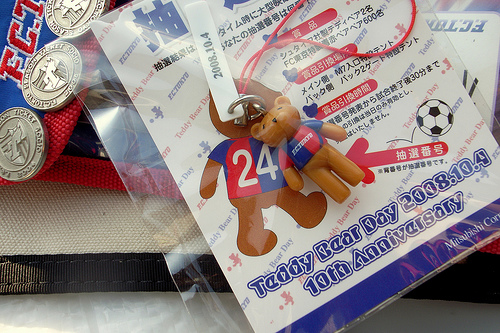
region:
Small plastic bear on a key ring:
[217, 0, 413, 214]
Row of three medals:
[2, 1, 97, 189]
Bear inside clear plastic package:
[54, 3, 489, 325]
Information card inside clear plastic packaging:
[72, 0, 493, 323]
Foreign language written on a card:
[131, 5, 447, 136]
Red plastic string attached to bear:
[222, 0, 419, 202]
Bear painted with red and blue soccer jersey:
[235, 91, 367, 216]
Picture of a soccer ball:
[395, 85, 467, 158]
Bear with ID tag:
[155, 1, 374, 208]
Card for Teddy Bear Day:
[187, 65, 493, 302]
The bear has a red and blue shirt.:
[261, 128, 371, 174]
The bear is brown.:
[227, 72, 371, 224]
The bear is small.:
[246, 98, 381, 194]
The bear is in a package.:
[110, 14, 497, 326]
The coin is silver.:
[21, 42, 103, 93]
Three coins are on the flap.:
[0, 9, 104, 194]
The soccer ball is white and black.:
[398, 97, 478, 145]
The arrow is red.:
[323, 132, 480, 194]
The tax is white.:
[179, 12, 261, 162]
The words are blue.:
[230, 177, 495, 279]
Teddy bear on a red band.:
[250, 95, 369, 202]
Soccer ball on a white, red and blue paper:
[416, 100, 453, 136]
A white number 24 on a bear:
[227, 143, 283, 185]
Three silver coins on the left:
[0, 0, 107, 182]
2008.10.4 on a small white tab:
[200, 28, 225, 80]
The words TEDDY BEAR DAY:
[245, 201, 402, 302]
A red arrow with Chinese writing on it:
[342, 137, 449, 185]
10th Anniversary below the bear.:
[269, 191, 464, 295]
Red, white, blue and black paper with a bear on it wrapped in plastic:
[87, 0, 497, 332]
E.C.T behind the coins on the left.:
[0, 0, 45, 86]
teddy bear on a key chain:
[0, 48, 460, 296]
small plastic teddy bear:
[267, 78, 354, 193]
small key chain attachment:
[125, 52, 370, 227]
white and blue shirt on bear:
[244, 104, 336, 198]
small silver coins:
[7, 45, 142, 150]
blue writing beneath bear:
[200, 158, 492, 322]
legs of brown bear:
[308, 158, 380, 203]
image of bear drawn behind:
[22, 45, 350, 269]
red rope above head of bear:
[290, 0, 415, 115]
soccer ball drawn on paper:
[375, 75, 483, 179]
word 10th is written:
[317, 275, 336, 282]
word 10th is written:
[319, 268, 339, 288]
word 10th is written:
[316, 278, 335, 296]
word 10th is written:
[316, 268, 328, 283]